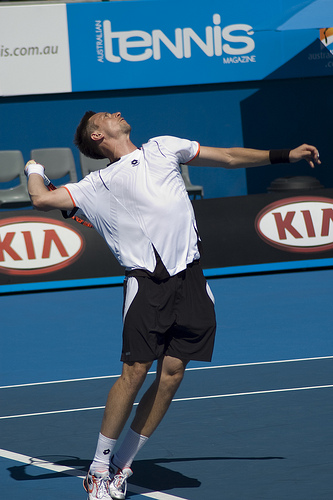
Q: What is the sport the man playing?
A: Tennis.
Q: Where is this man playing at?
A: Tennis court.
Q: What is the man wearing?
A: Tennis outfit.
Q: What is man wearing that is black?
A: Short.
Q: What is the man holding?
A: Racket.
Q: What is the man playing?
A: Tennis.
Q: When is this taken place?
A: During the day time.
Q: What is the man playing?
A: Tennis.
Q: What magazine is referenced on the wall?
A: Australian Tennis Magazine.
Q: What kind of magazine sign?
A: Australian.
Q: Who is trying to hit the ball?
A: Tennis player.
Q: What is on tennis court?
A: Shadow.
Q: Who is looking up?
A: Tennis player.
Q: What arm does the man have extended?
A: Left.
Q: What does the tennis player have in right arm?
A: Racket.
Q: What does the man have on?
A: Black short.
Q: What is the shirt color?
A: White.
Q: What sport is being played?
A: Tennis.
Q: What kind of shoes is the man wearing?
A: Sneakers.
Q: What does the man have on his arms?
A: Wristbands.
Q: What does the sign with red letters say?
A: Kia.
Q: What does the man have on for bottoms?
A: Shorts.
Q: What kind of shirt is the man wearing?
A: T-shirt.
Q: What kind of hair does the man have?
A: Brown.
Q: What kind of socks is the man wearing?
A: White.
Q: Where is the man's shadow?
A: Ground.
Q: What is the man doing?
A: Playing tennis.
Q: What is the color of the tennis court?
A: Blue.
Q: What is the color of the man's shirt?
A: White.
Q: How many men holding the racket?
A: One.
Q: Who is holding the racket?
A: A player.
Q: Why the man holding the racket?
A: To play.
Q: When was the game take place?
A: Daytime.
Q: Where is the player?
A: In the tennis court.